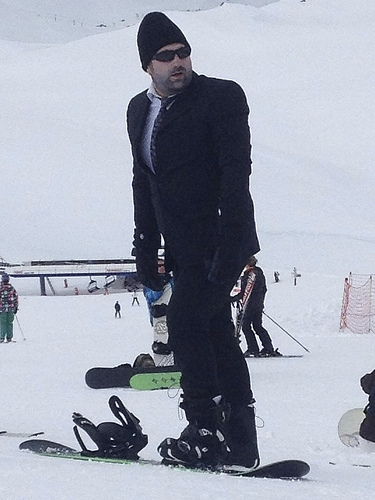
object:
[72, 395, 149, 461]
black binding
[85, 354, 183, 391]
snowboard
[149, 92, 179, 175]
tie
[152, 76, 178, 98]
neck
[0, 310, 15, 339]
pants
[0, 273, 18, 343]
person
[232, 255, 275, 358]
man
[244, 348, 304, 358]
skis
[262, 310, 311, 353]
ski pole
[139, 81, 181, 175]
shirt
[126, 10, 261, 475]
man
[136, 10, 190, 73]
cap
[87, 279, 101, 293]
empty chair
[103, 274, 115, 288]
empty chair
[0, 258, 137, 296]
chairlift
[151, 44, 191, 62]
glasses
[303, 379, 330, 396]
snow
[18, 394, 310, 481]
snowboard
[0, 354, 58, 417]
snow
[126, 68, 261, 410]
suit